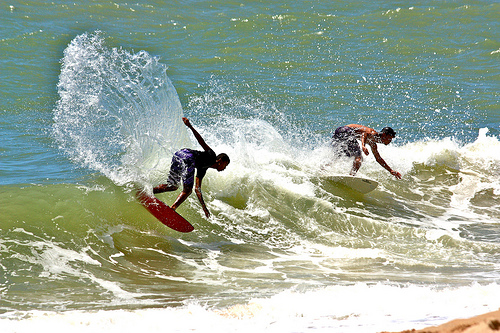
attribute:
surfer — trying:
[147, 116, 231, 219]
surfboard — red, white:
[123, 178, 197, 235]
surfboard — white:
[315, 173, 379, 202]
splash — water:
[46, 28, 196, 200]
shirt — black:
[186, 142, 214, 180]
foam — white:
[3, 221, 145, 309]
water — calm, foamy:
[1, 3, 500, 332]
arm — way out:
[180, 114, 217, 155]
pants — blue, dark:
[166, 147, 198, 201]